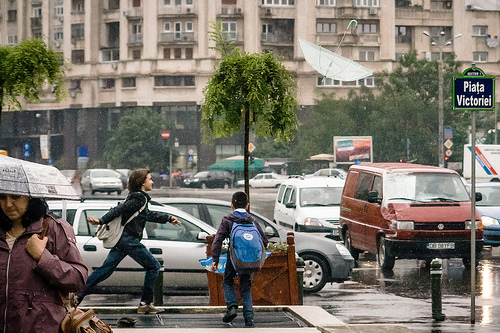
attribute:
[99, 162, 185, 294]
person — running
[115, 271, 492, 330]
street — busy, city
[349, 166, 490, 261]
van — red, brown, wrecked, big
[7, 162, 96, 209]
umbrella — gray, white, patterned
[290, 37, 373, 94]
umbrella — flying, blown, upside down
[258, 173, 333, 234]
van — white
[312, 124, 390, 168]
billboard — distance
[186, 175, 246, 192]
car — parked, black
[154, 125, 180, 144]
sign — red, round, white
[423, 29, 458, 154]
street light — overhead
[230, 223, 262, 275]
backpack — blue, grey, black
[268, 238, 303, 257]
plant — green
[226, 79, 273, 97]
leaves — green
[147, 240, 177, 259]
handle — black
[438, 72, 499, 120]
sign — black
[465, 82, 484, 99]
letters — white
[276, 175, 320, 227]
vehicle — white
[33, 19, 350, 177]
building — large, beige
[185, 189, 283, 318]
boy — walking, young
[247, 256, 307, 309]
planter — wooden, large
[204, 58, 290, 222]
tree — middle, green, small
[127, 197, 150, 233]
jacket — dark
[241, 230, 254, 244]
emblem — white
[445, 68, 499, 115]
street sign — blue, green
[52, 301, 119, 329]
purse — brown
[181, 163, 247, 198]
suv — parked, black